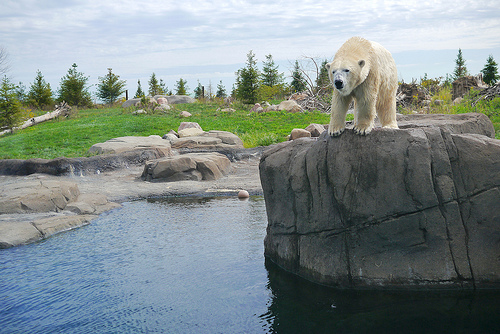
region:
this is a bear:
[301, 20, 420, 125]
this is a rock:
[264, 131, 491, 305]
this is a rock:
[0, 160, 85, 258]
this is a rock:
[86, 98, 168, 160]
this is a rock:
[137, 91, 174, 116]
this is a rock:
[169, 104, 200, 145]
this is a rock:
[267, 95, 317, 123]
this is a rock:
[287, 121, 312, 143]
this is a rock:
[164, 111, 240, 165]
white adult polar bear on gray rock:
[320, 25, 412, 141]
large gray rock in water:
[244, 120, 498, 298]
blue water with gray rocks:
[8, 141, 320, 328]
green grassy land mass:
[16, 60, 486, 165]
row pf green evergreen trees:
[1, 38, 496, 127]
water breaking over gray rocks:
[77, 141, 296, 201]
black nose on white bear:
[328, 75, 350, 91]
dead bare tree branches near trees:
[296, 50, 339, 114]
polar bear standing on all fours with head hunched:
[328, 26, 401, 137]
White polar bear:
[325, 32, 400, 137]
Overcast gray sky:
[0, 0, 495, 35]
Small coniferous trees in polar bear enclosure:
[0, 50, 325, 130]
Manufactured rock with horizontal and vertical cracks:
[260, 110, 495, 290]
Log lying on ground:
[0, 100, 70, 135]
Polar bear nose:
[330, 75, 345, 90]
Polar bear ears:
[322, 57, 365, 67]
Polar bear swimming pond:
[3, 195, 263, 330]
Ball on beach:
[235, 186, 250, 197]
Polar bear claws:
[327, 121, 374, 137]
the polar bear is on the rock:
[296, 25, 413, 145]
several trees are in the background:
[4, 47, 496, 115]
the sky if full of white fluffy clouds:
[4, 8, 480, 57]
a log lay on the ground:
[1, 98, 73, 143]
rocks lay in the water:
[0, 99, 275, 254]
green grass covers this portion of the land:
[16, 83, 496, 153]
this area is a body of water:
[9, 171, 263, 332]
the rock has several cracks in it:
[265, 152, 482, 253]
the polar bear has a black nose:
[333, 73, 343, 88]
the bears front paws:
[323, 117, 381, 144]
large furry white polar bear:
[321, 38, 400, 135]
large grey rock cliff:
[259, 117, 497, 292]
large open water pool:
[2, 200, 499, 330]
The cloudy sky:
[6, 7, 486, 92]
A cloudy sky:
[3, 0, 498, 75]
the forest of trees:
[9, 42, 499, 117]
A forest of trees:
[8, 44, 498, 114]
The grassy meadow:
[5, 89, 496, 151]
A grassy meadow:
[9, 90, 496, 150]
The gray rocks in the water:
[6, 115, 245, 239]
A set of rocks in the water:
[7, 127, 247, 257]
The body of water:
[9, 173, 286, 332]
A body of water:
[15, 171, 276, 324]